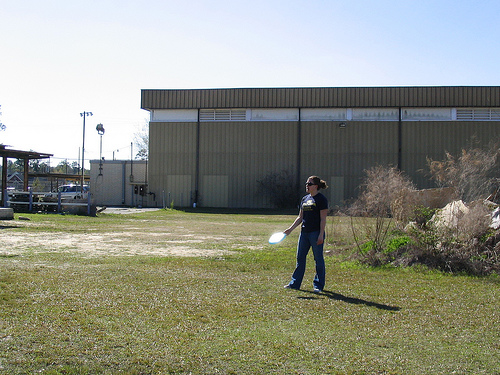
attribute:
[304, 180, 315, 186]
sunglasses — black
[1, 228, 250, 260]
spot — brown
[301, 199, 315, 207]
logo — yellow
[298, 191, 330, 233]
shirt — black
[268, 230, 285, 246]
frisbee — white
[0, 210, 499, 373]
grassy area — green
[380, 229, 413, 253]
bush — green, small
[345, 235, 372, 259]
bush — green, small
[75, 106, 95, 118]
lights — high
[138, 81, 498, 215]
building — tall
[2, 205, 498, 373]
grass — green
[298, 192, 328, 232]
t-shirt — black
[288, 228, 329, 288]
jeans — blue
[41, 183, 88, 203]
minivan — white, parked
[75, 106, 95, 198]
light — tall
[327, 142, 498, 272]
bushes — leafless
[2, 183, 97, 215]
fence — small, metal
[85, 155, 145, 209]
building — small, tan